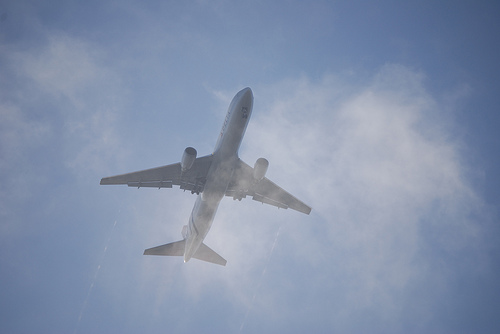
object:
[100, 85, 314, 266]
airplane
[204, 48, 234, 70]
sky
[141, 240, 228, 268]
tail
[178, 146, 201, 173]
engine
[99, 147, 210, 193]
wing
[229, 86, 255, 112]
nose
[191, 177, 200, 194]
landing gear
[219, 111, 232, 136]
writing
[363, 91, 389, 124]
cloud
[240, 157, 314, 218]
wing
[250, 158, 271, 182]
engine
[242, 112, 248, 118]
wheel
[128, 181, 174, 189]
landing flap